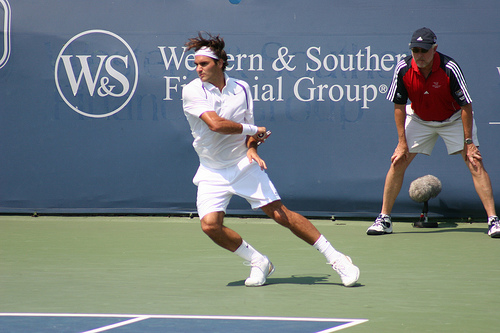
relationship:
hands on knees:
[388, 137, 488, 173] [190, 202, 311, 239]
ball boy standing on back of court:
[366, 27, 500, 238] [1, 212, 498, 329]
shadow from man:
[222, 264, 364, 296] [180, 47, 358, 287]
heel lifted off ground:
[257, 255, 276, 271] [0, 216, 498, 331]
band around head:
[189, 45, 229, 64] [174, 29, 236, 86]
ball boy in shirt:
[366, 27, 500, 238] [408, 41, 459, 95]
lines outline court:
[13, 308, 402, 329] [0, 214, 500, 333]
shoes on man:
[235, 254, 362, 291] [180, 47, 358, 287]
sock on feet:
[316, 227, 352, 270] [266, 201, 406, 301]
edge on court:
[331, 308, 367, 327] [6, 319, 374, 332]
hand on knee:
[448, 140, 495, 177] [379, 155, 413, 177]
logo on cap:
[413, 34, 425, 42] [405, 25, 438, 50]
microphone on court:
[398, 171, 454, 229] [1, 212, 498, 329]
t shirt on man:
[179, 77, 255, 170] [180, 47, 358, 287]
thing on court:
[407, 172, 459, 227] [1, 212, 498, 329]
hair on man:
[176, 28, 233, 70] [160, 25, 380, 295]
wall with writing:
[0, 0, 496, 219] [152, 39, 410, 113]